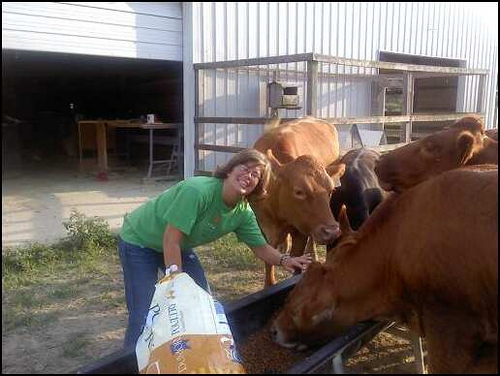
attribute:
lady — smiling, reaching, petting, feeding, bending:
[118, 150, 311, 347]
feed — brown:
[235, 306, 303, 375]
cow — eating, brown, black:
[271, 163, 499, 371]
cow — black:
[326, 145, 390, 244]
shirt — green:
[118, 175, 266, 252]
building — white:
[3, 3, 499, 181]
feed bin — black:
[64, 272, 391, 374]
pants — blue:
[118, 234, 208, 348]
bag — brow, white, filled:
[135, 264, 245, 374]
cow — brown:
[245, 116, 339, 285]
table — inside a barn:
[80, 117, 179, 183]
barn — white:
[3, 3, 498, 180]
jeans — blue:
[119, 235, 213, 351]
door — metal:
[3, 4, 182, 61]